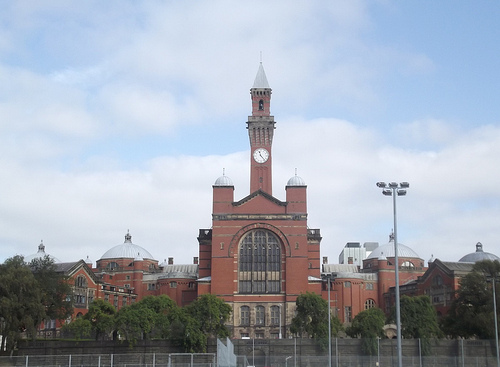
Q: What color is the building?
A: Red.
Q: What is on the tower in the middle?
A: A clock.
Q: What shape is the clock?
A: Round.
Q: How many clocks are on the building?
A: 1.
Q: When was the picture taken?
A: 11:25.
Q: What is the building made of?
A: Brick.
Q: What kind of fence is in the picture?
A: Chain link.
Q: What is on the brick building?
A: A dome roof.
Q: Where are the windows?
A: On the building.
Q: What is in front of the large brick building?
A: Lots of trees.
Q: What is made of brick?
A: The church.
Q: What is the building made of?
A: Brick.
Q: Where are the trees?
A: In front of the building.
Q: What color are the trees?
A: Green.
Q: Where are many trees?
A: In front of the building.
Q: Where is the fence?
A: In front of the building.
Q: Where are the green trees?
A: Behind the wall.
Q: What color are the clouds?
A: White.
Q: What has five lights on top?
A: Pole.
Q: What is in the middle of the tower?
A: Clock.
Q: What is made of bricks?
A: Building.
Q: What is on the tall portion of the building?
A: A clock.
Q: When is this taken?
A: Afternoon.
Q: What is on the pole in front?
A: Lights.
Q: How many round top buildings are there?
A: Four.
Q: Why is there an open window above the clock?
A: Holds the bell.